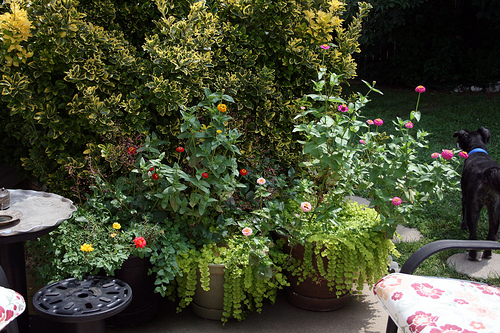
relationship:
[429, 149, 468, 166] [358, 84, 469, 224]
flowers on bush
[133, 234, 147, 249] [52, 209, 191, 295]
flower on bush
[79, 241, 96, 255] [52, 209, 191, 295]
flower on bush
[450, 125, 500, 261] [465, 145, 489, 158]
dog wearing collar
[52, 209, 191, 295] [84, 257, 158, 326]
bush in pot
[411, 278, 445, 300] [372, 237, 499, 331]
flower on chair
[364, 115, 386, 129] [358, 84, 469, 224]
flowers on bush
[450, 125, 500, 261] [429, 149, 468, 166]
dog near flowers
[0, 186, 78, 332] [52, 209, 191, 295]
table next to bush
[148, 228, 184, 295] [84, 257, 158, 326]
leaves in pot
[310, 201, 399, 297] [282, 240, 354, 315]
plant in pot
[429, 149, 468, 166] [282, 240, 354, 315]
flowers on pot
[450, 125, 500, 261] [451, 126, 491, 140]
dog has ears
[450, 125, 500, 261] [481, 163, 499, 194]
dog has tail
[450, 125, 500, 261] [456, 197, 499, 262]
dog has legs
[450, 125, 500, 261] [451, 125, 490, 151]
dog has head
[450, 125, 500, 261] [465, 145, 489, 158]
dog has collar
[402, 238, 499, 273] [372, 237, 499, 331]
arm rest on chair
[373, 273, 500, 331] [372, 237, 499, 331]
cushion on chair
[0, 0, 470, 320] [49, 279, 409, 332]
plants on ground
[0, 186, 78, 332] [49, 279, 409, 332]
table on ground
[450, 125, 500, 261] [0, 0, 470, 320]
dog next to plants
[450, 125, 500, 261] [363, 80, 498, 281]
dog looking at grass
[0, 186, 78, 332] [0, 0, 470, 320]
table next to plants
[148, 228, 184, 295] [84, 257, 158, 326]
leaves hanging off pot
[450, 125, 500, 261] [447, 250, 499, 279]
dog standing on stepping stone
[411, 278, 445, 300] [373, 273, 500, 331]
flower on cushion